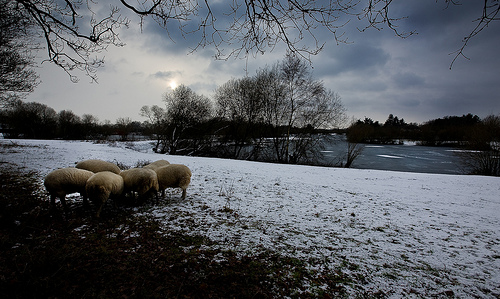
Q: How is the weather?
A: It is stormy.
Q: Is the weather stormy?
A: Yes, it is stormy.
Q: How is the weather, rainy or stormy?
A: It is stormy.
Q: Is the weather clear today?
A: No, it is stormy.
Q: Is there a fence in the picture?
A: No, there are no fences.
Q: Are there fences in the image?
A: No, there are no fences.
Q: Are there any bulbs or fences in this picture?
A: No, there are no fences or bulbs.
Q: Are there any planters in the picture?
A: No, there are no planters.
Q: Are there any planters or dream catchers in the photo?
A: No, there are no planters or dream catchers.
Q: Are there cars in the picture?
A: No, there are no cars.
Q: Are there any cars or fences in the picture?
A: No, there are no cars or fences.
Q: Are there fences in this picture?
A: No, there are no fences.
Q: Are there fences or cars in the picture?
A: No, there are no fences or cars.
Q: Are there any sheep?
A: Yes, there is a sheep.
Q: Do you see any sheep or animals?
A: Yes, there is a sheep.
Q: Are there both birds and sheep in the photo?
A: No, there is a sheep but no birds.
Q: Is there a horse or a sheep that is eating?
A: Yes, the sheep is eating.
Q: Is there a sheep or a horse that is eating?
A: Yes, the sheep is eating.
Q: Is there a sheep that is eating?
A: Yes, there is a sheep that is eating.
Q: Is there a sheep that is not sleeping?
A: Yes, there is a sheep that is eating.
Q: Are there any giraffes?
A: No, there are no giraffes.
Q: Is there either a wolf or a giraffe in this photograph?
A: No, there are no giraffes or wolves.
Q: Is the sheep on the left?
A: Yes, the sheep is on the left of the image.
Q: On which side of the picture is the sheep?
A: The sheep is on the left of the image.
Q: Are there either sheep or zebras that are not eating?
A: No, there is a sheep but it is eating.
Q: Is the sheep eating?
A: Yes, the sheep is eating.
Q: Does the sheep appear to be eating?
A: Yes, the sheep is eating.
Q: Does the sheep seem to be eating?
A: Yes, the sheep is eating.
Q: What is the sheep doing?
A: The sheep is eating.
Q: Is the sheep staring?
A: No, the sheep is eating.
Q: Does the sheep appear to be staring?
A: No, the sheep is eating.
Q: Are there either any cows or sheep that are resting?
A: No, there is a sheep but it is eating.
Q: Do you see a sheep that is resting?
A: No, there is a sheep but it is eating.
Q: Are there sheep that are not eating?
A: No, there is a sheep but it is eating.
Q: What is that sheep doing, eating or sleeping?
A: The sheep is eating.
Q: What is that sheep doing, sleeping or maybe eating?
A: The sheep is eating.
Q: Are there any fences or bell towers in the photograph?
A: No, there are no fences or bell towers.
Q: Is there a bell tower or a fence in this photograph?
A: No, there are no fences or bell towers.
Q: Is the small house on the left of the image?
A: Yes, the house is on the left of the image.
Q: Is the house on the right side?
A: No, the house is on the left of the image.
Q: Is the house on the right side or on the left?
A: The house is on the left of the image.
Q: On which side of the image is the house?
A: The house is on the left of the image.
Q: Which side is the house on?
A: The house is on the left of the image.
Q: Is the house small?
A: Yes, the house is small.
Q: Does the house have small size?
A: Yes, the house is small.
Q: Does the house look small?
A: Yes, the house is small.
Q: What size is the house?
A: The house is small.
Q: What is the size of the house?
A: The house is small.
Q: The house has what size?
A: The house is small.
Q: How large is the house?
A: The house is small.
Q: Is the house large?
A: No, the house is small.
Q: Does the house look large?
A: No, the house is small.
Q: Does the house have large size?
A: No, the house is small.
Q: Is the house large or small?
A: The house is small.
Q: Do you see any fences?
A: No, there are no fences.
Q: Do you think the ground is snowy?
A: Yes, the ground is snowy.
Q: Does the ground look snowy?
A: Yes, the ground is snowy.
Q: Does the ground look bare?
A: No, the ground is snowy.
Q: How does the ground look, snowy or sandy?
A: The ground is snowy.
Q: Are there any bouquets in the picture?
A: No, there are no bouquets.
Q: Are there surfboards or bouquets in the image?
A: No, there are no bouquets or surfboards.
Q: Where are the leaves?
A: The leaves are on the ground.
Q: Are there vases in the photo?
A: No, there are no vases.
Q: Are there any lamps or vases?
A: No, there are no vases or lamps.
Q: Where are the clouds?
A: The clouds are in the sky.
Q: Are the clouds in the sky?
A: Yes, the clouds are in the sky.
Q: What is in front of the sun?
A: The clouds are in front of the sun.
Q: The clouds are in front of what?
A: The clouds are in front of the sun.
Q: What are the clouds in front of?
A: The clouds are in front of the sun.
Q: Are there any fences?
A: No, there are no fences.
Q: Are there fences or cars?
A: No, there are no fences or cars.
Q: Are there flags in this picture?
A: No, there are no flags.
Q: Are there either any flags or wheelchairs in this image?
A: No, there are no flags or wheelchairs.